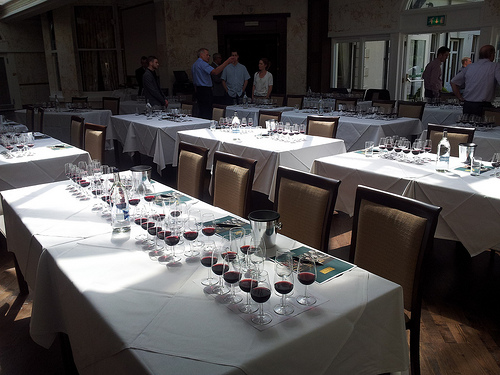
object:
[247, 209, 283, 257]
container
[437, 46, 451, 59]
hair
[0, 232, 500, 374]
floor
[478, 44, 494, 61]
head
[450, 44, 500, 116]
person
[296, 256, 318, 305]
glass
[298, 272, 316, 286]
wine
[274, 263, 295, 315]
glass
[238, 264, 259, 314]
glass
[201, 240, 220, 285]
glass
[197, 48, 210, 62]
head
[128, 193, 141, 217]
wine glasses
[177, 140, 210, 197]
chair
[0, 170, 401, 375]
table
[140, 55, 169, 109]
person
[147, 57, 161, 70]
head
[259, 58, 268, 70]
head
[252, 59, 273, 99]
person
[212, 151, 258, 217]
chair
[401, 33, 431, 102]
door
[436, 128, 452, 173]
bottle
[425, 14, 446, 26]
exit sign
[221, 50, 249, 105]
man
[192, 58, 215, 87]
blue shirt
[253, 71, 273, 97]
shirt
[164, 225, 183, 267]
glass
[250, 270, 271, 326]
glass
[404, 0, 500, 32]
wall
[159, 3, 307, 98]
wall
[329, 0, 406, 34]
wall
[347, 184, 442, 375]
chair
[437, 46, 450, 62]
head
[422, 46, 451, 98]
person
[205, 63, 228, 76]
arm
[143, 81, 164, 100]
arm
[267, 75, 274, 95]
arm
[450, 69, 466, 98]
arm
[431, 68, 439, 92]
arm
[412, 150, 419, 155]
wine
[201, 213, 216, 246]
wine glasses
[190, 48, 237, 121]
man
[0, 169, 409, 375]
cloth